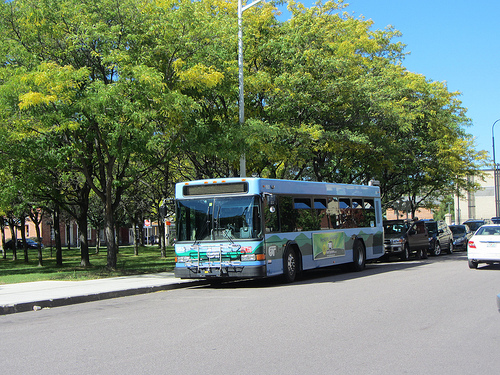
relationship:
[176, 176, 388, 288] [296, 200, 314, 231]
bus has passenger window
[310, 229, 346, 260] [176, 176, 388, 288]
advertisement on bus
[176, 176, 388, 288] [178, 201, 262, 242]
bus has windshield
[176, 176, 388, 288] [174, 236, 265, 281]
bus has bumper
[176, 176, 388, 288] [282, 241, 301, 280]
bus has left front wheel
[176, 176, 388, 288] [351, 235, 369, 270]
bus has left back wheel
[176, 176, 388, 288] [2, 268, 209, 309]
bus parked near sidewalk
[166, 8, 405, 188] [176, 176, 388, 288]
tree behind bus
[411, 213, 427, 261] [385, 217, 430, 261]
person getting into car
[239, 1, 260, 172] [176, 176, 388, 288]
light post behind bus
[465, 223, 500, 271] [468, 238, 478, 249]
vehicle has tail light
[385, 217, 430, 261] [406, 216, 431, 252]
car has door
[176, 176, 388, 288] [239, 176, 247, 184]
bus has circle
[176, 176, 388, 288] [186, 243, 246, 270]
bus has bike rack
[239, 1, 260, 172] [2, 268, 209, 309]
light post on sidewalk